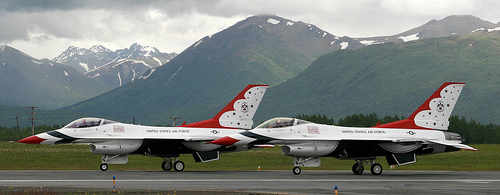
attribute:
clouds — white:
[85, 7, 132, 39]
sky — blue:
[139, 6, 194, 41]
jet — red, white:
[13, 79, 277, 174]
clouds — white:
[33, 29, 160, 76]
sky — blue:
[0, 0, 497, 128]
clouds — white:
[394, 1, 488, 18]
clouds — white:
[62, 3, 193, 81]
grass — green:
[7, 137, 499, 175]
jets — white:
[26, 80, 461, 167]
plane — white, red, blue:
[225, 82, 477, 191]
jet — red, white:
[210, 78, 475, 176]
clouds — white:
[0, 0, 500, 58]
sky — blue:
[4, 1, 499, 41]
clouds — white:
[74, 13, 194, 43]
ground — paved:
[0, 169, 500, 193]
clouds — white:
[1, 2, 498, 25]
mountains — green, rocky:
[256, 32, 499, 132]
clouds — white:
[6, 7, 200, 40]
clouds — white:
[156, 7, 239, 40]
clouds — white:
[33, 1, 140, 38]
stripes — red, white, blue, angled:
[16, 131, 76, 146]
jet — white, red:
[204, 68, 484, 183]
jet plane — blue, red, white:
[46, 94, 275, 171]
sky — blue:
[99, 7, 221, 59]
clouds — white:
[86, 17, 174, 67]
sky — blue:
[71, 24, 190, 72]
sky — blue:
[117, 15, 199, 51]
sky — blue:
[4, 3, 484, 62]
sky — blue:
[0, 4, 415, 64]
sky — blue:
[2, 13, 390, 47]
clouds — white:
[0, 0, 221, 60]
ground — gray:
[2, 162, 484, 192]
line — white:
[2, 174, 484, 184]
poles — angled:
[5, 102, 37, 134]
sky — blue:
[11, 7, 168, 56]